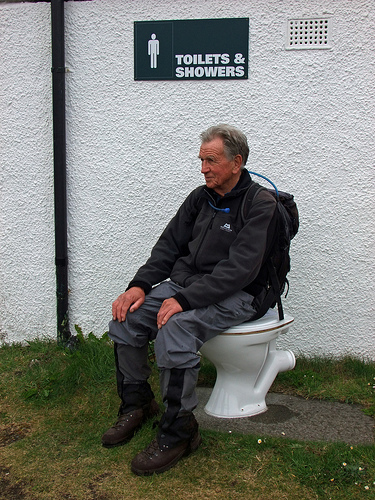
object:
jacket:
[124, 168, 279, 314]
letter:
[175, 54, 184, 65]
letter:
[183, 54, 193, 66]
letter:
[192, 54, 197, 64]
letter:
[198, 54, 205, 64]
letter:
[205, 53, 213, 65]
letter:
[220, 54, 230, 65]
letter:
[175, 66, 184, 78]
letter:
[194, 66, 204, 77]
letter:
[204, 66, 218, 77]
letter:
[218, 66, 226, 77]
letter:
[225, 66, 236, 77]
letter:
[236, 66, 245, 78]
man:
[98, 123, 302, 478]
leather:
[130, 433, 182, 470]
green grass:
[0, 309, 375, 499]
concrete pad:
[192, 386, 374, 447]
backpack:
[257, 184, 300, 322]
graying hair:
[198, 122, 251, 172]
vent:
[284, 13, 334, 51]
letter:
[184, 66, 194, 77]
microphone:
[208, 170, 280, 215]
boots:
[101, 399, 202, 476]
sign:
[133, 17, 250, 81]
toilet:
[198, 303, 297, 419]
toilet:
[174, 52, 231, 65]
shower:
[175, 66, 245, 78]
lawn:
[0, 323, 375, 498]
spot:
[198, 375, 375, 449]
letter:
[213, 53, 221, 65]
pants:
[108, 278, 257, 418]